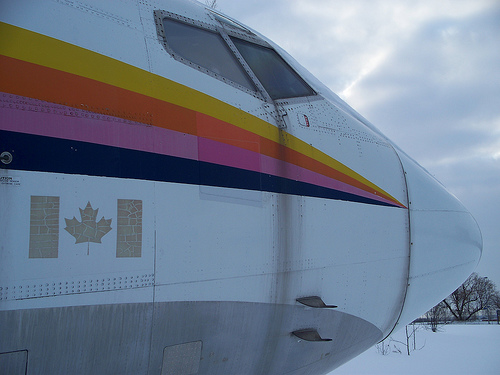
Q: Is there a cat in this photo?
A: No, there are no cats.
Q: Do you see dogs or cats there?
A: No, there are no cats or dogs.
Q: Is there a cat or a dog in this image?
A: No, there are no cats or dogs.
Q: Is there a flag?
A: Yes, there is a flag.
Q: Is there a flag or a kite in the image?
A: Yes, there is a flag.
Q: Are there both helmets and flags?
A: No, there is a flag but no helmets.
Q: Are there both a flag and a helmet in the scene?
A: No, there is a flag but no helmets.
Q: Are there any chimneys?
A: No, there are no chimneys.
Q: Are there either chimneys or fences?
A: No, there are no chimneys or fences.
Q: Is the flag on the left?
A: Yes, the flag is on the left of the image.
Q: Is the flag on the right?
A: No, the flag is on the left of the image.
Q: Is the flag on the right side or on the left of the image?
A: The flag is on the left of the image.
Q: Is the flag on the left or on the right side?
A: The flag is on the left of the image.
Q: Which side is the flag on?
A: The flag is on the left of the image.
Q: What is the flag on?
A: The flag is on the airplane.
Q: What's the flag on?
A: The flag is on the airplane.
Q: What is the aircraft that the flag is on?
A: The aircraft is an airplane.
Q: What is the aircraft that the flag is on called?
A: The aircraft is an airplane.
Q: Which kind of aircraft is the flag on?
A: The flag is on the airplane.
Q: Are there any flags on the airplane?
A: Yes, there is a flag on the airplane.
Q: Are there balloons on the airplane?
A: No, there is a flag on the airplane.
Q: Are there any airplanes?
A: Yes, there is an airplane.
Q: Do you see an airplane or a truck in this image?
A: Yes, there is an airplane.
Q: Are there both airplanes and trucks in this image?
A: No, there is an airplane but no trucks.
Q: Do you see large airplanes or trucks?
A: Yes, there is a large airplane.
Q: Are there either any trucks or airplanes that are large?
A: Yes, the airplane is large.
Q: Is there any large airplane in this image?
A: Yes, there is a large airplane.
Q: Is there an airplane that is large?
A: Yes, there is an airplane that is large.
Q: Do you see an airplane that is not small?
A: Yes, there is a large airplane.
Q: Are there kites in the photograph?
A: No, there are no kites.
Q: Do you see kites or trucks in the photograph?
A: No, there are no kites or trucks.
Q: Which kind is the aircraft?
A: The aircraft is an airplane.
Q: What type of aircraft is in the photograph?
A: The aircraft is an airplane.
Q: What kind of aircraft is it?
A: The aircraft is an airplane.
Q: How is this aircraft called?
A: That is an airplane.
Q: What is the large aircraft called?
A: The aircraft is an airplane.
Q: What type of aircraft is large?
A: The aircraft is an airplane.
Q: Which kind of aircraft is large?
A: The aircraft is an airplane.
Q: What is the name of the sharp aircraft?
A: The aircraft is an airplane.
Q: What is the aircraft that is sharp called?
A: The aircraft is an airplane.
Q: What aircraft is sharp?
A: The aircraft is an airplane.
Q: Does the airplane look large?
A: Yes, the airplane is large.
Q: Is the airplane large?
A: Yes, the airplane is large.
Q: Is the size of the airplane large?
A: Yes, the airplane is large.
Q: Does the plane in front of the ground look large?
A: Yes, the airplane is large.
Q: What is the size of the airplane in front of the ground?
A: The plane is large.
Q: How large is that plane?
A: The plane is large.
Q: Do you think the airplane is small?
A: No, the airplane is large.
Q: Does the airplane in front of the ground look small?
A: No, the airplane is large.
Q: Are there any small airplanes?
A: No, there is an airplane but it is large.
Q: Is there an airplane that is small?
A: No, there is an airplane but it is large.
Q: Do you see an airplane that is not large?
A: No, there is an airplane but it is large.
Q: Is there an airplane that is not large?
A: No, there is an airplane but it is large.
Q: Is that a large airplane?
A: Yes, that is a large airplane.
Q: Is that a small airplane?
A: No, that is a large airplane.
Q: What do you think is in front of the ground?
A: The airplane is in front of the ground.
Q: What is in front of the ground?
A: The airplane is in front of the ground.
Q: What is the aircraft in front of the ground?
A: The aircraft is an airplane.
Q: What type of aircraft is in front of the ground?
A: The aircraft is an airplane.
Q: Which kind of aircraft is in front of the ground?
A: The aircraft is an airplane.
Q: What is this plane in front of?
A: The plane is in front of the ground.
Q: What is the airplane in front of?
A: The plane is in front of the ground.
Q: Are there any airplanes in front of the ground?
A: Yes, there is an airplane in front of the ground.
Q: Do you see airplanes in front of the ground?
A: Yes, there is an airplane in front of the ground.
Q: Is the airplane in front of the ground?
A: Yes, the airplane is in front of the ground.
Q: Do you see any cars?
A: No, there are no cars.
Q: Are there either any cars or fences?
A: No, there are no cars or fences.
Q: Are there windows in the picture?
A: Yes, there is a window.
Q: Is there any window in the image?
A: Yes, there is a window.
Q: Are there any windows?
A: Yes, there is a window.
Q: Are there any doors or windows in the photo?
A: Yes, there is a window.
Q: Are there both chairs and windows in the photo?
A: No, there is a window but no chairs.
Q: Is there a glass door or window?
A: Yes, there is a glass window.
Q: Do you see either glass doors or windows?
A: Yes, there is a glass window.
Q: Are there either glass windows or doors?
A: Yes, there is a glass window.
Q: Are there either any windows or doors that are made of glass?
A: Yes, the window is made of glass.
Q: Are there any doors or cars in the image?
A: No, there are no cars or doors.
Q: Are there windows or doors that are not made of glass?
A: No, there is a window but it is made of glass.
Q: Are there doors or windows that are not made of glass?
A: No, there is a window but it is made of glass.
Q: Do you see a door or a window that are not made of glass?
A: No, there is a window but it is made of glass.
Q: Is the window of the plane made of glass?
A: Yes, the window is made of glass.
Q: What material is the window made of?
A: The window is made of glass.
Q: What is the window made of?
A: The window is made of glass.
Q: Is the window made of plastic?
A: No, the window is made of glass.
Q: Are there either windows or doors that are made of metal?
A: No, there is a window but it is made of glass.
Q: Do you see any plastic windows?
A: No, there is a window but it is made of glass.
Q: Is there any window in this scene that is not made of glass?
A: No, there is a window but it is made of glass.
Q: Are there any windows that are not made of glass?
A: No, there is a window but it is made of glass.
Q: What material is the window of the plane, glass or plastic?
A: The window is made of glass.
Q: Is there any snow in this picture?
A: Yes, there is snow.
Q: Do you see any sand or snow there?
A: Yes, there is snow.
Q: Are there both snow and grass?
A: No, there is snow but no grass.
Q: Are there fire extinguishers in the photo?
A: No, there are no fire extinguishers.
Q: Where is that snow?
A: The snow is on the ground.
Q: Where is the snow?
A: The snow is on the ground.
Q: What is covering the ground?
A: The snow is covering the ground.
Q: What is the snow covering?
A: The snow is covering the ground.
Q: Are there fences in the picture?
A: No, there are no fences.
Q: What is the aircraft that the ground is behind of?
A: The aircraft is an airplane.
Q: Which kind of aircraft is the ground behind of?
A: The ground is behind the plane.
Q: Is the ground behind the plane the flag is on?
A: Yes, the ground is behind the plane.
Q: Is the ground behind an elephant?
A: No, the ground is behind the plane.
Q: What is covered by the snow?
A: The ground is covered by the snow.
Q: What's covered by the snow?
A: The ground is covered by the snow.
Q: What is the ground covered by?
A: The ground is covered by the snow.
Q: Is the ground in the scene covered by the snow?
A: Yes, the ground is covered by the snow.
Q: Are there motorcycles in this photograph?
A: No, there are no motorcycles.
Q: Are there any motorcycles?
A: No, there are no motorcycles.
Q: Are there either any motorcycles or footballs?
A: No, there are no motorcycles or footballs.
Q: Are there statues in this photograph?
A: No, there are no statues.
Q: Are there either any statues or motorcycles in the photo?
A: No, there are no statues or motorcycles.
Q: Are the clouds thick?
A: Yes, the clouds are thick.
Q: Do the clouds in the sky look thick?
A: Yes, the clouds are thick.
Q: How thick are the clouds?
A: The clouds are thick.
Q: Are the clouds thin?
A: No, the clouds are thick.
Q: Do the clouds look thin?
A: No, the clouds are thick.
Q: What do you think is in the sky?
A: The clouds are in the sky.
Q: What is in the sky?
A: The clouds are in the sky.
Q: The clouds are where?
A: The clouds are in the sky.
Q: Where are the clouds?
A: The clouds are in the sky.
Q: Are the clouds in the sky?
A: Yes, the clouds are in the sky.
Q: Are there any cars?
A: No, there are no cars.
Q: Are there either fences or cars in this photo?
A: No, there are no cars or fences.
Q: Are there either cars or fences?
A: No, there are no cars or fences.